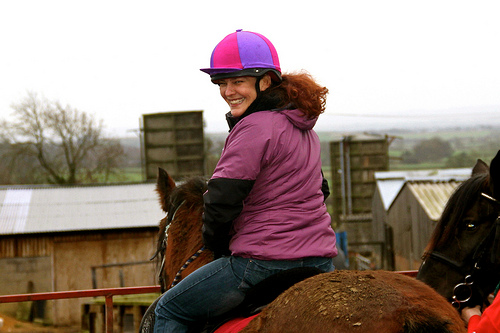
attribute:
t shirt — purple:
[202, 104, 346, 264]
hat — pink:
[199, 28, 292, 84]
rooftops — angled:
[350, 152, 499, 287]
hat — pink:
[199, 23, 283, 80]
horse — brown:
[156, 165, 467, 331]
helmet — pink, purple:
[192, 19, 282, 81]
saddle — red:
[207, 311, 254, 332]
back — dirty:
[291, 269, 426, 323]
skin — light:
[213, 70, 277, 120]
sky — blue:
[2, 56, 499, 144]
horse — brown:
[161, 178, 443, 323]